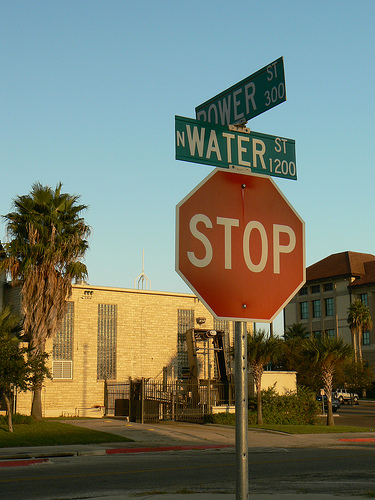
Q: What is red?
A: A stop sign.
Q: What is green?
A: The grass.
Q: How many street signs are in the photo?
A: Two.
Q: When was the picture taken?
A: During the day.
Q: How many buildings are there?
A: Two.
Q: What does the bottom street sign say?
A: "WATER ST".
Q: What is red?
A: The curb.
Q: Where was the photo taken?
A: On the street.